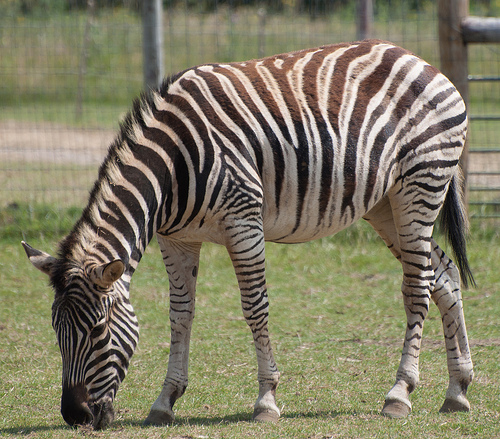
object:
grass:
[1, 1, 497, 131]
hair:
[44, 70, 180, 294]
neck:
[59, 134, 170, 278]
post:
[438, 0, 465, 102]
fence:
[0, 0, 500, 236]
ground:
[432, 150, 452, 175]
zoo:
[0, 0, 500, 439]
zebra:
[21, 37, 478, 432]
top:
[462, 15, 499, 42]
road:
[0, 119, 500, 191]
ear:
[21, 240, 58, 276]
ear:
[89, 258, 124, 289]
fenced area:
[0, 0, 53, 436]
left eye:
[89, 323, 105, 338]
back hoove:
[385, 375, 417, 401]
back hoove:
[437, 370, 471, 410]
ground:
[238, 32, 318, 87]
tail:
[438, 162, 479, 291]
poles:
[138, 0, 165, 97]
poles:
[356, 0, 373, 40]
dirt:
[334, 330, 362, 347]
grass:
[0, 200, 500, 439]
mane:
[54, 73, 178, 261]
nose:
[60, 399, 91, 427]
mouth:
[93, 400, 105, 431]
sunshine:
[36, 138, 484, 427]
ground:
[1, 325, 498, 439]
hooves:
[144, 397, 470, 424]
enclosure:
[0, 0, 500, 439]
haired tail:
[438, 207, 479, 290]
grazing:
[20, 38, 480, 432]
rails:
[16, 211, 34, 253]